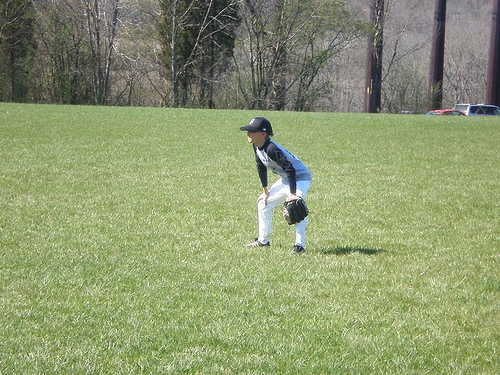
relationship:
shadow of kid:
[347, 247, 375, 259] [211, 118, 316, 249]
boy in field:
[211, 118, 316, 249] [157, 108, 212, 162]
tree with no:
[161, 25, 268, 101] [251, 9, 333, 96]